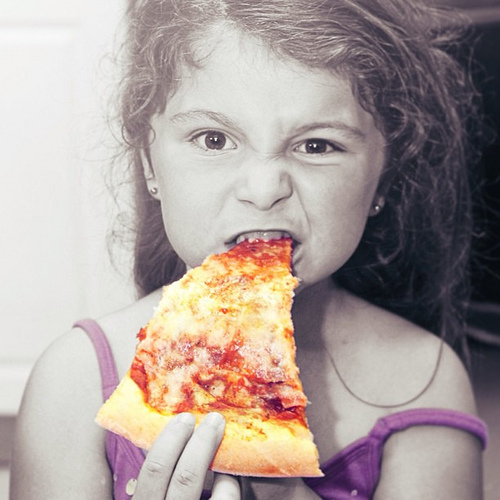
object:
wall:
[15, 127, 75, 243]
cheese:
[168, 322, 234, 359]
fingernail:
[170, 409, 194, 428]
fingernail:
[195, 405, 225, 430]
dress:
[74, 316, 488, 498]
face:
[140, 20, 387, 298]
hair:
[95, 1, 483, 366]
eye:
[288, 132, 351, 158]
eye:
[186, 124, 242, 154]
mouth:
[217, 225, 305, 269]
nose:
[231, 154, 293, 212]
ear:
[368, 150, 394, 218]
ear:
[139, 148, 159, 201]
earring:
[148, 186, 159, 196]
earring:
[370, 204, 380, 215]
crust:
[91, 373, 326, 480]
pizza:
[95, 241, 326, 479]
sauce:
[131, 326, 310, 426]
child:
[9, 0, 486, 499]